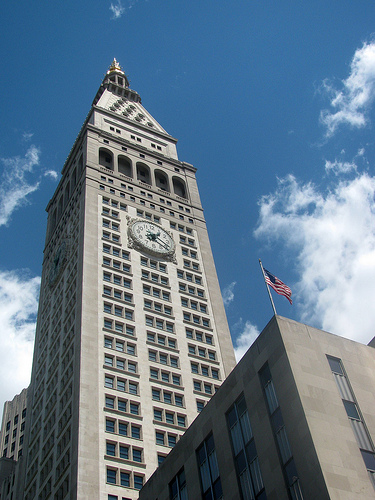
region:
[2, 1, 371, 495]
blue of daytime sky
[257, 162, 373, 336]
white cloud in sky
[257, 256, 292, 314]
american flag on pole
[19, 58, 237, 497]
city building with clock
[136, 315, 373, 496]
corner of city building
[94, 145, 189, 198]
row of arched openings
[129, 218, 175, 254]
clock with white face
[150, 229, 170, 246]
hands on clock face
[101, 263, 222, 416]
rows of three windows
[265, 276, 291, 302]
red stripes on flag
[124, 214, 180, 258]
a clock on a building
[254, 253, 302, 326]
A flag on a building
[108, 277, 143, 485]
a row of windows on a building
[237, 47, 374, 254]
white clouds in a sky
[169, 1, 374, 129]
a blue and white sky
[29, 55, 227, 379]
a gray concerte building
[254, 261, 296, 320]
a flag on a pole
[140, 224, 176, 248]
black hands on a clock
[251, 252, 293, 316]
a red white and blue flag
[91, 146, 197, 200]
archway opening on a building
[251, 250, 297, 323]
american flag on building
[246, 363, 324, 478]
part of a building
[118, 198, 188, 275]
clock on a building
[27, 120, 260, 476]
part of a tall building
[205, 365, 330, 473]
part of a building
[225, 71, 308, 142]
part of blue sky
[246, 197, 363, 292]
clouds in blue sky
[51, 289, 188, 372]
part of a building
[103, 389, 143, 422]
windows on a building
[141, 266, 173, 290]
windows on a building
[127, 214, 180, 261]
white clock on building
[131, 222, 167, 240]
clock has brown numbers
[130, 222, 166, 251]
clock has green hands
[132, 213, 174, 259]
grey frame around clock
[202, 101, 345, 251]
blue and white sky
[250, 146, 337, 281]
wispy clouds in sky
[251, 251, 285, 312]
US flag on pole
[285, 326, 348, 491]
grey stone wall on building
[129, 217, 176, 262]
a clock on the tower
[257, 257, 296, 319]
the American flag is flying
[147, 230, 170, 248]
clock hand on the clock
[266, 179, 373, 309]
white clouds in the sky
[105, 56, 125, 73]
the top of the tower is pointed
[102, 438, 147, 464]
three windows are connected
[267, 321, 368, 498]
concrete block wall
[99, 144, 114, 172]
an archway on the building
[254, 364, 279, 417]
the window is closed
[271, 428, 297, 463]
white curtains in the window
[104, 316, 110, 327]
A window on a building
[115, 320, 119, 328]
A window on a building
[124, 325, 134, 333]
A window on a building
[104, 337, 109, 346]
A window on a building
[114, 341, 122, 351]
A window on a building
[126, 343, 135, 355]
A window on a building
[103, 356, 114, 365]
A window on a building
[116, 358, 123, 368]
A window on a building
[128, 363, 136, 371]
A window on a building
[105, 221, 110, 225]
A window on a building